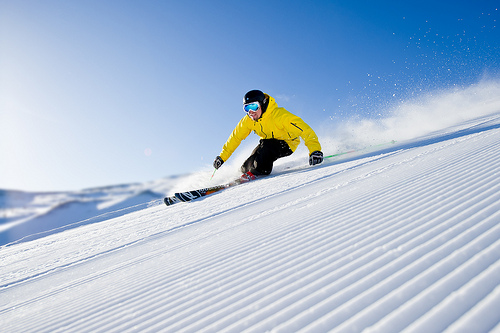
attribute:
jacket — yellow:
[217, 96, 321, 153]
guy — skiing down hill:
[161, 77, 327, 186]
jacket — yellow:
[190, 81, 362, 183]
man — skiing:
[205, 85, 335, 187]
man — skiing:
[127, 28, 332, 196]